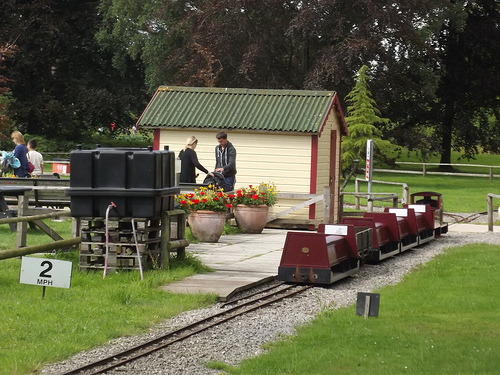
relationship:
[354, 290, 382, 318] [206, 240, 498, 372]
object in grass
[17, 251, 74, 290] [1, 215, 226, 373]
sign on grass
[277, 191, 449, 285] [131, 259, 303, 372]
train on tracks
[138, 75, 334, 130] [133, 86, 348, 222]
green roof on building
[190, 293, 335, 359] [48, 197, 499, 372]
gravel along tracks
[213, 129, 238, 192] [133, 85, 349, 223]
people near building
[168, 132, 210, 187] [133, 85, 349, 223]
person near building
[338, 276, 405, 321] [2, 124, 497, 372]
object in ground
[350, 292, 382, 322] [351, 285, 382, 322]
handle has object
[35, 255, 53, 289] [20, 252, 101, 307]
display on board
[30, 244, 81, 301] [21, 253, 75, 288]
number on board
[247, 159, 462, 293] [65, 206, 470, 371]
train on track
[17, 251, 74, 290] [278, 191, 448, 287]
sign by train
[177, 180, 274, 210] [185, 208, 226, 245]
flowers inside item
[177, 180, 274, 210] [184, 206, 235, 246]
flowers inside item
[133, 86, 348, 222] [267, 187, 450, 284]
building by train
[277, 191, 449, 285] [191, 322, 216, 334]
train on tracks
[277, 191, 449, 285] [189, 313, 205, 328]
train on tracks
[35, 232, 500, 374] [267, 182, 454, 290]
gravel by train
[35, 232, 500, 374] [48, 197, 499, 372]
gravel by tracks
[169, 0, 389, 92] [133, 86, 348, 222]
tree behind building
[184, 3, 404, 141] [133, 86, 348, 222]
tree behind building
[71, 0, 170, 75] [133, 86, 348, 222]
tree behind building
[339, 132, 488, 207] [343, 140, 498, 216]
fence around yard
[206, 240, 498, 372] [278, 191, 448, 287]
grass near train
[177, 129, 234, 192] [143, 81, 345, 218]
people standing by building